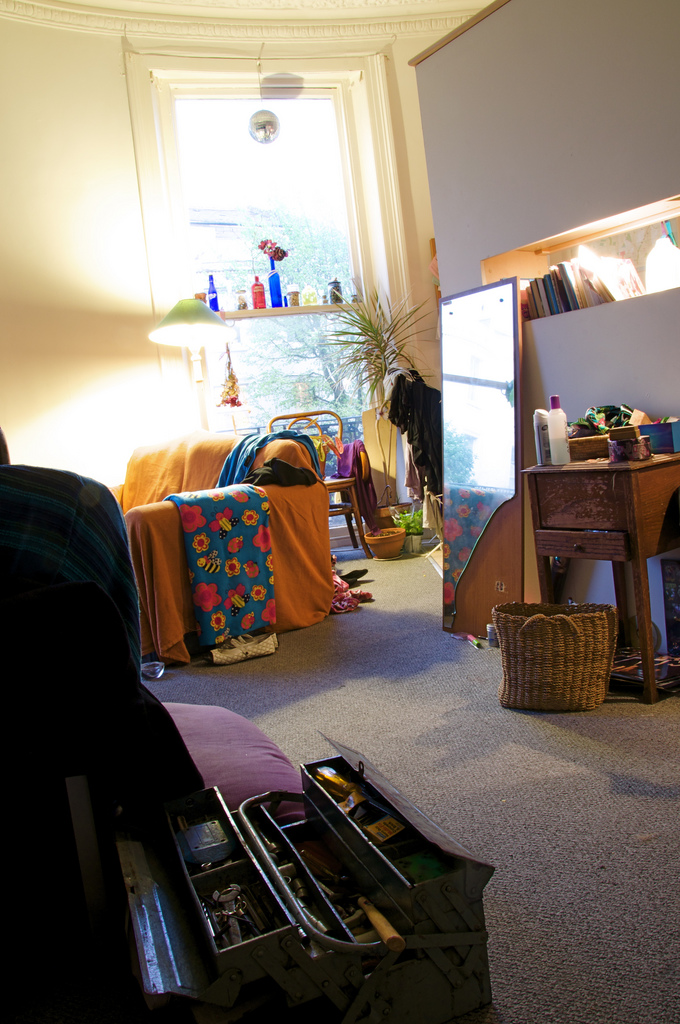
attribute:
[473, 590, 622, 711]
basket — brown, wicker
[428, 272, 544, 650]
mirror — broken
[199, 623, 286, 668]
shoes — white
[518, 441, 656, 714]
table — brown, wooden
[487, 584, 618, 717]
wicker basket — empty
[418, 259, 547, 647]
mirror — broken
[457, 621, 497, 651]
tube — mascara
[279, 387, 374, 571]
chair — wooden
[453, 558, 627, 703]
bag — brown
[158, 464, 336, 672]
blanket — colorful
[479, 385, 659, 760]
table — small, wooden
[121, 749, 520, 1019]
box — tool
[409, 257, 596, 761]
mirror — tall, standing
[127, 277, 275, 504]
lamp — white, standing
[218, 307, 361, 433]
glass — clean, clear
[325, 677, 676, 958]
carpet — light grey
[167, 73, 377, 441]
window — white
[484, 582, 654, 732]
basket — brown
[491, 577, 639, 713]
basket — brown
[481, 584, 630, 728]
wicker basket — brown , wicker 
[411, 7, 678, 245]
white wall — white 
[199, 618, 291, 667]
white shoe — White 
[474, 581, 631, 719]
brown basket — brown 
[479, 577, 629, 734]
wicker basket — brown , wicker 